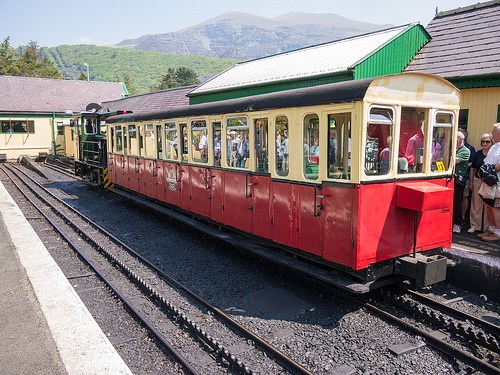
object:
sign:
[436, 161, 446, 173]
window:
[301, 111, 321, 183]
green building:
[182, 20, 433, 107]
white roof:
[185, 20, 421, 95]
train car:
[103, 69, 462, 295]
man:
[451, 129, 471, 235]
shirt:
[454, 143, 471, 178]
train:
[67, 71, 462, 297]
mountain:
[0, 41, 243, 101]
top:
[104, 70, 463, 189]